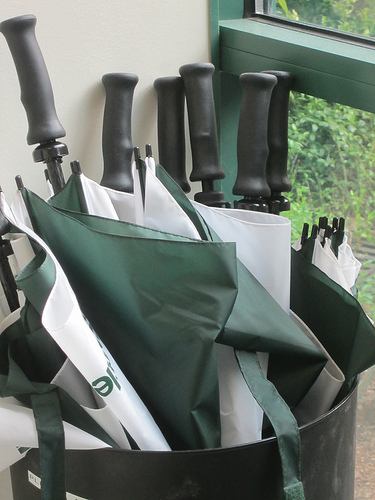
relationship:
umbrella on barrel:
[0, 10, 374, 464] [10, 376, 355, 498]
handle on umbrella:
[1, 15, 63, 145] [78, 238, 188, 323]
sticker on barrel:
[24, 464, 86, 498] [10, 376, 355, 498]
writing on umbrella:
[80, 310, 123, 397] [0, 13, 329, 499]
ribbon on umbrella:
[235, 348, 307, 498] [0, 47, 211, 446]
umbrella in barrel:
[0, 10, 374, 500] [10, 376, 355, 498]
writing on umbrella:
[80, 310, 123, 397] [19, 54, 354, 458]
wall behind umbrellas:
[0, 0, 213, 206] [0, 55, 370, 449]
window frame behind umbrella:
[204, 0, 373, 223] [0, 10, 374, 464]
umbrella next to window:
[0, 10, 374, 500] [205, 4, 374, 306]